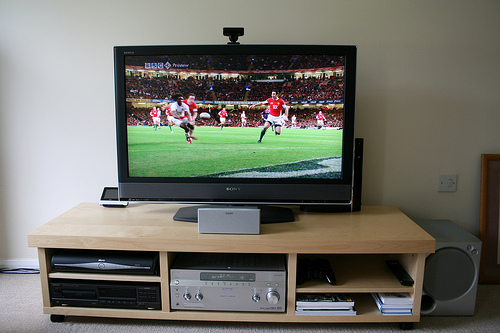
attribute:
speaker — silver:
[412, 218, 482, 317]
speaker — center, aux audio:
[196, 205, 263, 235]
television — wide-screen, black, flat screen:
[113, 45, 360, 222]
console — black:
[40, 274, 168, 319]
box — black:
[44, 252, 164, 277]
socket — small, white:
[426, 166, 498, 217]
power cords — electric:
[0, 265, 43, 275]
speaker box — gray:
[409, 215, 481, 317]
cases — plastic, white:
[294, 295, 356, 318]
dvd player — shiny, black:
[52, 253, 153, 275]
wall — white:
[4, 2, 481, 197]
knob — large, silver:
[267, 294, 280, 307]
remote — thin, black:
[383, 258, 415, 285]